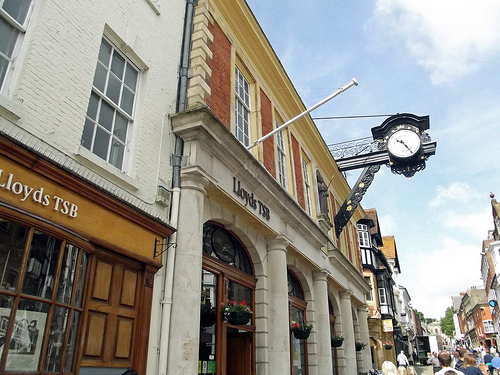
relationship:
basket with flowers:
[229, 302, 255, 327] [230, 300, 251, 309]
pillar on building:
[170, 175, 209, 373] [187, 0, 372, 374]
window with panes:
[77, 21, 149, 179] [81, 97, 141, 157]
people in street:
[438, 340, 499, 374] [424, 368, 432, 372]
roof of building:
[366, 207, 379, 233] [187, 0, 372, 374]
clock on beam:
[367, 112, 437, 178] [335, 151, 388, 171]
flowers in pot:
[230, 300, 251, 309] [224, 315, 256, 325]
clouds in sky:
[388, 1, 484, 86] [283, 17, 367, 68]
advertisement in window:
[3, 306, 42, 371] [3, 210, 91, 373]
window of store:
[3, 210, 91, 373] [2, 146, 156, 373]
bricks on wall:
[35, 74, 56, 80] [2, 1, 179, 217]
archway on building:
[204, 201, 271, 264] [187, 0, 372, 374]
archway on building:
[283, 252, 318, 312] [187, 0, 372, 374]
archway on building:
[324, 285, 342, 313] [187, 0, 372, 374]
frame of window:
[5, 206, 107, 252] [3, 210, 91, 373]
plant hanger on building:
[229, 302, 255, 327] [187, 0, 372, 374]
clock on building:
[367, 112, 437, 178] [187, 0, 372, 374]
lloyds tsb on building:
[231, 177, 274, 222] [187, 0, 372, 374]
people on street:
[438, 340, 499, 374] [424, 368, 432, 372]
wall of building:
[2, 1, 179, 217] [187, 0, 372, 374]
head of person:
[438, 353, 453, 365] [435, 351, 463, 373]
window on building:
[77, 21, 149, 179] [187, 0, 372, 374]